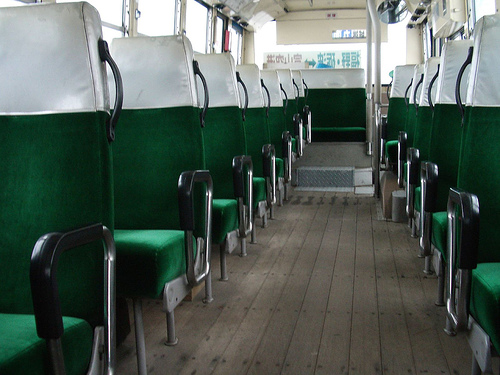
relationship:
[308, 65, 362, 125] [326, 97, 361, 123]
back of seat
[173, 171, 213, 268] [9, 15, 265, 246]
arms on seat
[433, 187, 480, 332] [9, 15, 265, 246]
arms on seat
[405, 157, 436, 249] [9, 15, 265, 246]
arms on seat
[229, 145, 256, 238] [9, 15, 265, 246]
arms on seat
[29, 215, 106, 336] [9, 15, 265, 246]
arm rest on seat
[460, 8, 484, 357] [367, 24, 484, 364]
seat in row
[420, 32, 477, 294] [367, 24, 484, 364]
seat in row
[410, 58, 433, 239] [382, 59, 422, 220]
seat in seat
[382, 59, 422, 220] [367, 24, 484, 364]
seat in row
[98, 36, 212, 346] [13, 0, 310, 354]
seat in row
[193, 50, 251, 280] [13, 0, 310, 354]
seat in row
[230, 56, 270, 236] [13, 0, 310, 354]
seat in row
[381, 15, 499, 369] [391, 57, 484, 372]
bus seats in row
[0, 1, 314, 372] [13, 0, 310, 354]
bus seats in row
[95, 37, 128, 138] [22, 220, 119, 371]
skier has handle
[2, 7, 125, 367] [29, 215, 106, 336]
bus seat has arm rest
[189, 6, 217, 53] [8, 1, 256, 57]
window in row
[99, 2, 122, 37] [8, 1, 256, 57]
window in row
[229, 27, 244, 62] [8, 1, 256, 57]
window in row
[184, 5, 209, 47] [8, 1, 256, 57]
window in row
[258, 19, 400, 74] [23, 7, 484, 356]
windshield front of bus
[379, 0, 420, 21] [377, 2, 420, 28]
reflection on mirror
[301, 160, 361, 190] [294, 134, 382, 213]
grate on back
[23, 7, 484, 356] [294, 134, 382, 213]
bus has back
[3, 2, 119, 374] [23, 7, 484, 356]
seating on bus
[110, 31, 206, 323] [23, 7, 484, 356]
seating on bus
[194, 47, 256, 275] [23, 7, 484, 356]
seating on bus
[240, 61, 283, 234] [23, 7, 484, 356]
seating on bus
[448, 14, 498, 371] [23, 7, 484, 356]
seating on bus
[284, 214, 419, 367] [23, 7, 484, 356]
hardwood floors in bus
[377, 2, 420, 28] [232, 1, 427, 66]
mirror mounted on ceiling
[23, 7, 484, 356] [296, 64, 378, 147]
bus has back seat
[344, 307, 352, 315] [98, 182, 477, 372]
nail in floor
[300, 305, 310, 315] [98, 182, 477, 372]
nail in floor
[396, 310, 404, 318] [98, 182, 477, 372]
nail in floor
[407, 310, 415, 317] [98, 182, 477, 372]
nail in floor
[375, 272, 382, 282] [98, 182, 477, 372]
nail in floor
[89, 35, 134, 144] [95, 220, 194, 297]
handle on seat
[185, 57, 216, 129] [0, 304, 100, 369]
handle on seat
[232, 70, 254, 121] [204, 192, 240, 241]
handle on seat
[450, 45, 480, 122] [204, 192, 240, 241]
handle on seat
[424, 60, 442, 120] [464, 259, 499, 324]
handle on seat